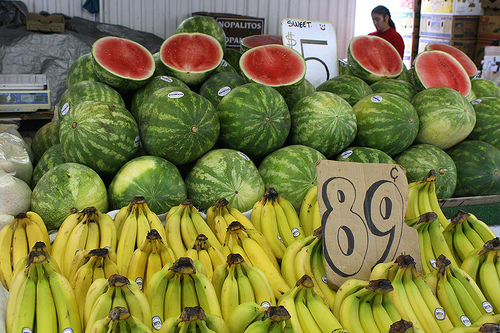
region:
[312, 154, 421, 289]
cardboard 89 cent sign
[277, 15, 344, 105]
fruit stand price sign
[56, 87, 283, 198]
group of whole, uncut watermelon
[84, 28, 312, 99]
three watermelon cut in half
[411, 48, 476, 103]
line of seeds in a cut watermelon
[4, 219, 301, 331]
group of banana bunches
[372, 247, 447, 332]
yellow ripe banana bunch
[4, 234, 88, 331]
slightly green banana bunch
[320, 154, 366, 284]
number 8 drawn on cardboard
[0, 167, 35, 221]
cantaloupe half out of frame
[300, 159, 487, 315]
this is a piece of cardboard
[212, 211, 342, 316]
this is a bunch of bananas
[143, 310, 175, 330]
this is a sticker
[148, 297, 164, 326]
the sticker is round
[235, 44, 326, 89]
the watermelon is sliced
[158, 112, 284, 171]
this is a large watermelon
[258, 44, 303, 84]
the fruit is pink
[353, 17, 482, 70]
this is a man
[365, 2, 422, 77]
the man is wearing red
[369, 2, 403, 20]
this is long hair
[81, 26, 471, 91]
A row of watermelon halves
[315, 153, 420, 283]
A brown sign with 89 cents on it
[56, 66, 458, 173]
A large stack of watermelons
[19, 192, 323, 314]
A large pile of bananas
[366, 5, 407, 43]
A man in the background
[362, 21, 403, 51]
A red tee shirt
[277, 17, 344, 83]
A white sign with sweet and $5 on it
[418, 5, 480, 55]
Stack of boxes on the right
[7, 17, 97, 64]
A cover or canvas on left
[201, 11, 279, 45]
A black against the white wall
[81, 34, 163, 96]
watermelon sliced in half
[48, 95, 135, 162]
a large whole watermelon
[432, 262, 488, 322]
bundle of not ripped bananas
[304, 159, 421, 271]
sign showing price of .89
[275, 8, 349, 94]
sign showing a price of $5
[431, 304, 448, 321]
sticker on a banana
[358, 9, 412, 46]
man wearing red shirt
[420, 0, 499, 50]
tall boxes of fruit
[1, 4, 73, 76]
gray tarp used for covering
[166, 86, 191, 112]
sticker on a watermelon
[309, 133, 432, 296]
a sign advertising 89 cents.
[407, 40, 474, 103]
a cut in half water melon.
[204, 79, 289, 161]
a large water melon.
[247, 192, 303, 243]
a bunch of ripe bananas.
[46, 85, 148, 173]
a water melon in a pile.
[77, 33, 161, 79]
a half of a water melon.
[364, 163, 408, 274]
a large hand drawn 9.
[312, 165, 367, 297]
a large hand drawn 8.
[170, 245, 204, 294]
the end of a banana bunch.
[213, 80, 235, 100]
a sticker on a water melon.